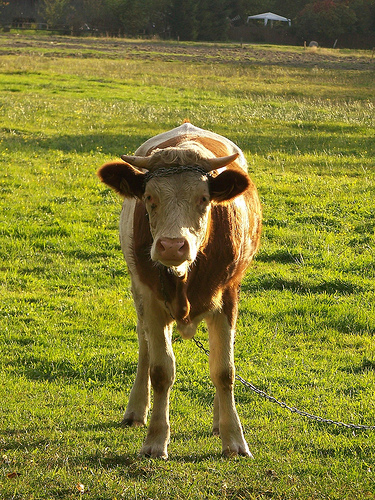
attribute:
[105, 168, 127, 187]
fur — brown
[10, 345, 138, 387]
shadow — faint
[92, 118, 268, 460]
cow — brown, white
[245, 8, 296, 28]
tent — white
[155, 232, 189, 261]
nose — pink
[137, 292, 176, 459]
front leg — white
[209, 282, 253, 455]
front leg — white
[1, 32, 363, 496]
grass — green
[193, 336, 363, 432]
chain — metal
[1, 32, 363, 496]
field — green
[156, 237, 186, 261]
nose — pink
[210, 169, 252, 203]
left ear — brown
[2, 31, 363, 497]
area — large